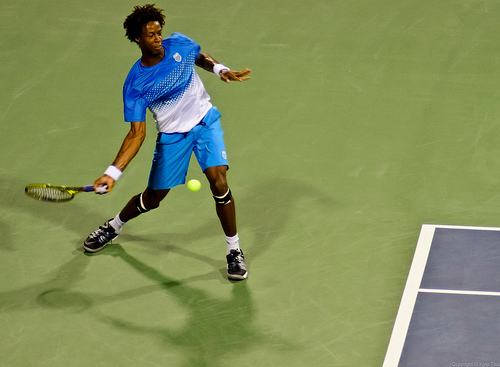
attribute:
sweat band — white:
[103, 162, 122, 181]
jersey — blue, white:
[123, 31, 207, 151]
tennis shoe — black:
[212, 238, 266, 288]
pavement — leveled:
[301, 54, 498, 258]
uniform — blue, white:
[120, 30, 230, 190]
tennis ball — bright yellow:
[187, 177, 199, 189]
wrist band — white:
[211, 61, 228, 76]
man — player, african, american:
[82, 3, 252, 279]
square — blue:
[381, 191, 495, 365]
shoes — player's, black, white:
[49, 207, 305, 310]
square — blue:
[389, 227, 499, 366]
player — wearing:
[81, 8, 253, 283]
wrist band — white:
[105, 161, 122, 180]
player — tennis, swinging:
[67, 0, 262, 295]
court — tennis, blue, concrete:
[0, 2, 498, 365]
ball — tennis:
[185, 177, 201, 189]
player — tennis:
[89, 20, 280, 292]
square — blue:
[415, 227, 499, 298]